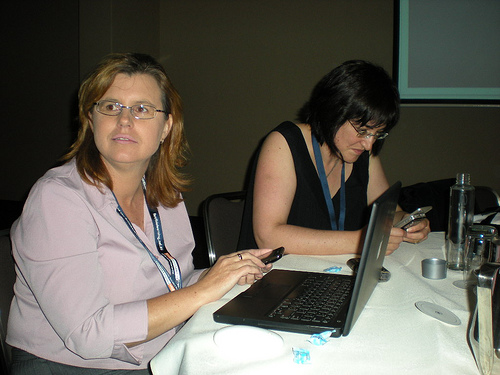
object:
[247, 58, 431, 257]
woman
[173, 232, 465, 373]
table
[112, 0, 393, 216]
tan walls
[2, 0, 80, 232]
wall